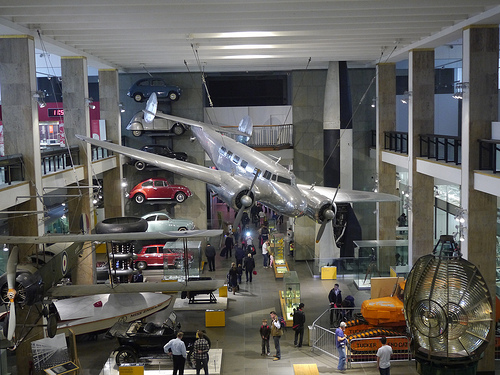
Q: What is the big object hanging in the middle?
A: An airplane.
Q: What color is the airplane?
A: Silver.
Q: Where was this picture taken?
A: A museum.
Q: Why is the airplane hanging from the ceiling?
A: On display.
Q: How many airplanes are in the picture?
A: One.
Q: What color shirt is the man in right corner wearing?
A: White.